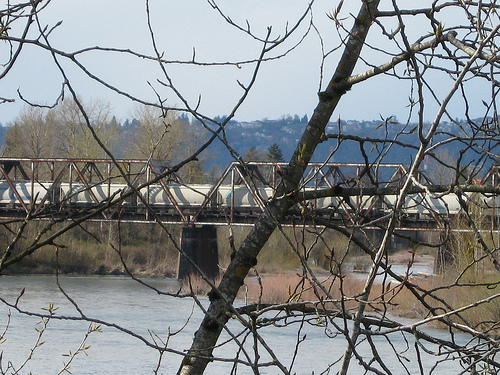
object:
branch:
[372, 0, 499, 20]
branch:
[346, 29, 498, 85]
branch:
[295, 184, 500, 201]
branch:
[233, 302, 499, 368]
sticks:
[452, 247, 500, 284]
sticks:
[460, 348, 499, 374]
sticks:
[144, 79, 166, 121]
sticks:
[420, 136, 496, 156]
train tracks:
[0, 199, 497, 218]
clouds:
[123, 24, 387, 118]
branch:
[343, 42, 483, 359]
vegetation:
[0, 221, 174, 278]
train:
[0, 179, 499, 219]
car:
[0, 171, 56, 203]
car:
[59, 182, 131, 209]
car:
[134, 182, 214, 209]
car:
[213, 186, 304, 207]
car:
[384, 182, 477, 214]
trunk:
[173, 0, 374, 372]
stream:
[0, 265, 499, 375]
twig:
[71, 46, 295, 65]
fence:
[0, 156, 498, 234]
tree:
[3, 102, 62, 190]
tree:
[126, 95, 182, 190]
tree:
[266, 138, 286, 183]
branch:
[80, 37, 154, 69]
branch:
[0, 296, 290, 375]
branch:
[263, 0, 314, 53]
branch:
[110, 242, 192, 299]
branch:
[33, 10, 223, 295]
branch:
[173, 0, 375, 375]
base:
[174, 224, 219, 280]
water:
[0, 268, 497, 370]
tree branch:
[363, 292, 499, 338]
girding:
[228, 168, 233, 223]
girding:
[145, 162, 150, 220]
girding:
[30, 158, 35, 215]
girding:
[491, 170, 496, 228]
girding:
[272, 166, 276, 192]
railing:
[0, 157, 150, 164]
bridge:
[57, 201, 241, 228]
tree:
[242, 142, 262, 182]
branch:
[143, 0, 272, 192]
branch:
[71, 2, 314, 68]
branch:
[321, 132, 475, 187]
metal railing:
[230, 161, 399, 167]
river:
[0, 260, 500, 374]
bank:
[1, 218, 498, 375]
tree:
[175, 139, 204, 182]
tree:
[61, 92, 119, 182]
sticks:
[252, 266, 263, 313]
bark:
[236, 230, 271, 256]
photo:
[0, 0, 500, 375]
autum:
[0, 0, 500, 375]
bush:
[446, 188, 499, 336]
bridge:
[2, 184, 489, 284]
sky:
[0, 0, 500, 136]